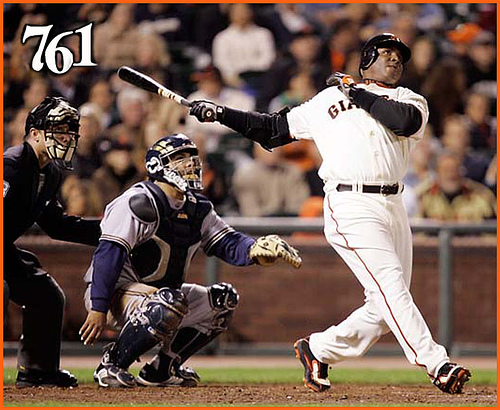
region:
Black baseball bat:
[114, 62, 217, 123]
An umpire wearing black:
[1, 95, 83, 386]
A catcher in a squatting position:
[78, 132, 299, 388]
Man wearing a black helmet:
[356, 31, 408, 88]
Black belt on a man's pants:
[322, 174, 408, 201]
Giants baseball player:
[270, 30, 473, 395]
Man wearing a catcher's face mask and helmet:
[143, 128, 204, 193]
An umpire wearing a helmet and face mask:
[23, 95, 85, 177]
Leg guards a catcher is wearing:
[110, 283, 240, 370]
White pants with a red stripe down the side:
[303, 181, 456, 368]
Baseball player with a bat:
[104, 27, 487, 387]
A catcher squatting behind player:
[87, 117, 290, 387]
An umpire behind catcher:
[10, 98, 86, 393]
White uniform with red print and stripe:
[286, 75, 458, 368]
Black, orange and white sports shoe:
[293, 335, 331, 390]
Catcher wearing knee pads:
[137, 278, 207, 341]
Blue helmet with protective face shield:
[132, 127, 214, 197]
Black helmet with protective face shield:
[27, 100, 87, 175]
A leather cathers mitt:
[242, 223, 302, 268]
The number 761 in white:
[18, 21, 100, 77]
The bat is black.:
[107, 59, 219, 129]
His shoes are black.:
[288, 332, 472, 396]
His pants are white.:
[298, 190, 440, 382]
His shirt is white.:
[297, 78, 432, 190]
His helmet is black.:
[348, 20, 397, 60]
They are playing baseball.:
[92, 15, 485, 392]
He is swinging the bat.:
[110, 13, 470, 408]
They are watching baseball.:
[23, 10, 496, 212]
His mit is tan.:
[240, 224, 300, 291]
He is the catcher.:
[72, 120, 282, 387]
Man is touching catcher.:
[0, 94, 302, 409]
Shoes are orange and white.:
[290, 336, 340, 396]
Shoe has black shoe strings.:
[292, 332, 335, 394]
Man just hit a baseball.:
[112, 32, 486, 403]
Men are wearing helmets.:
[1, 27, 495, 409]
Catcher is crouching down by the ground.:
[65, 133, 307, 392]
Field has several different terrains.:
[2, 353, 496, 409]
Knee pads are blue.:
[141, 285, 188, 337]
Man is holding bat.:
[105, 33, 475, 397]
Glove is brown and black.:
[249, 230, 304, 272]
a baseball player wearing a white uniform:
[264, 35, 469, 390]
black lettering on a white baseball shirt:
[328, 90, 395, 120]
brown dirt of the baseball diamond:
[208, 378, 280, 401]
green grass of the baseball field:
[233, 365, 275, 383]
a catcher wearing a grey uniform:
[91, 142, 273, 389]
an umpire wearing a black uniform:
[10, 105, 108, 390]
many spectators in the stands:
[124, 5, 302, 102]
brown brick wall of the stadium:
[250, 275, 317, 323]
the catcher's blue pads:
[156, 195, 191, 277]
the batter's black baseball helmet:
[356, 26, 411, 74]